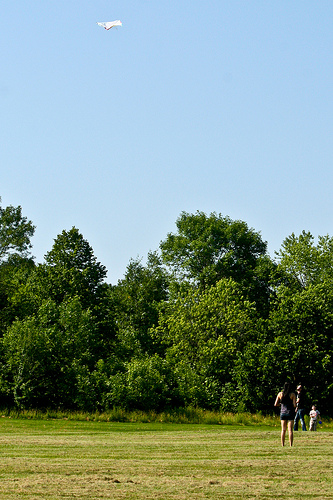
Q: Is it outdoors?
A: Yes, it is outdoors.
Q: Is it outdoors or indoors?
A: It is outdoors.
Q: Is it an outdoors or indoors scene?
A: It is outdoors.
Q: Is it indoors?
A: No, it is outdoors.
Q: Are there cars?
A: No, there are no cars.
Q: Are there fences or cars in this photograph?
A: No, there are no cars or fences.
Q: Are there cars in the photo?
A: No, there are no cars.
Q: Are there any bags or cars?
A: No, there are no cars or bags.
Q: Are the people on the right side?
A: Yes, the people are on the right of the image.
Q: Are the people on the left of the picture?
A: No, the people are on the right of the image.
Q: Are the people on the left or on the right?
A: The people are on the right of the image.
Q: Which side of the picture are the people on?
A: The people are on the right of the image.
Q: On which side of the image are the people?
A: The people are on the right of the image.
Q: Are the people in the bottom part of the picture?
A: Yes, the people are in the bottom of the image.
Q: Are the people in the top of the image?
A: No, the people are in the bottom of the image.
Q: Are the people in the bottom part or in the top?
A: The people are in the bottom of the image.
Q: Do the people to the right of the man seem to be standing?
A: Yes, the people are standing.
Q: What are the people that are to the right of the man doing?
A: The people are standing.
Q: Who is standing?
A: The people are standing.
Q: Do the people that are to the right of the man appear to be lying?
A: No, the people are standing.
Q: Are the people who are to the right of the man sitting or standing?
A: The people are standing.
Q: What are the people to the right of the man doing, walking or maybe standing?
A: The people are standing.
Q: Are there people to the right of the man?
A: Yes, there are people to the right of the man.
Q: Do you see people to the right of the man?
A: Yes, there are people to the right of the man.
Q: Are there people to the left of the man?
A: No, the people are to the right of the man.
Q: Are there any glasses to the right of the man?
A: No, there are people to the right of the man.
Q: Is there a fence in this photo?
A: No, there are no fences.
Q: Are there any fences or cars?
A: No, there are no fences or cars.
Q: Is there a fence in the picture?
A: No, there are no fences.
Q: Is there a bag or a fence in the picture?
A: No, there are no fences or bags.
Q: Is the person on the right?
A: Yes, the person is on the right of the image.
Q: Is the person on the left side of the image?
A: No, the person is on the right of the image.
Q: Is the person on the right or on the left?
A: The person is on the right of the image.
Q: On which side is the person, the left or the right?
A: The person is on the right of the image.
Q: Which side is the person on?
A: The person is on the right of the image.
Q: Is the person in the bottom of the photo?
A: Yes, the person is in the bottom of the image.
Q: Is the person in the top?
A: No, the person is in the bottom of the image.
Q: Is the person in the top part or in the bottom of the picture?
A: The person is in the bottom of the image.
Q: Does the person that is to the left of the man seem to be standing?
A: Yes, the person is standing.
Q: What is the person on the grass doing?
A: The person is standing.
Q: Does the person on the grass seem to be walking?
A: No, the person is standing.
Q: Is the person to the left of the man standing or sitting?
A: The person is standing.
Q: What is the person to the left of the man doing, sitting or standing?
A: The person is standing.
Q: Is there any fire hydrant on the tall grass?
A: No, there is a person on the grass.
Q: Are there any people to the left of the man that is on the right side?
A: Yes, there is a person to the left of the man.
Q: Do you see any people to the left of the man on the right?
A: Yes, there is a person to the left of the man.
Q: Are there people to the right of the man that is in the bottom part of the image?
A: No, the person is to the left of the man.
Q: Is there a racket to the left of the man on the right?
A: No, there is a person to the left of the man.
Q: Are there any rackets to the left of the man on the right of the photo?
A: No, there is a person to the left of the man.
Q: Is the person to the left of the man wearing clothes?
A: Yes, the person is wearing clothes.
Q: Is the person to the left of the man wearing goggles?
A: No, the person is wearing clothes.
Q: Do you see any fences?
A: No, there are no fences.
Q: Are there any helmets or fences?
A: No, there are no fences or helmets.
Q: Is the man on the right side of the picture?
A: Yes, the man is on the right of the image.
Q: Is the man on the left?
A: No, the man is on the right of the image.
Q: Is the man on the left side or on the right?
A: The man is on the right of the image.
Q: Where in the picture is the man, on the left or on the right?
A: The man is on the right of the image.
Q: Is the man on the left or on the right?
A: The man is on the right of the image.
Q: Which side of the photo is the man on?
A: The man is on the right of the image.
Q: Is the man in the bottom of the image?
A: Yes, the man is in the bottom of the image.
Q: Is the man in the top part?
A: No, the man is in the bottom of the image.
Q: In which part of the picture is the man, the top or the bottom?
A: The man is in the bottom of the image.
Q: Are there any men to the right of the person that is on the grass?
A: Yes, there is a man to the right of the person.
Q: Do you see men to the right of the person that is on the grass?
A: Yes, there is a man to the right of the person.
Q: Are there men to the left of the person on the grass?
A: No, the man is to the right of the person.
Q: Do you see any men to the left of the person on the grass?
A: No, the man is to the right of the person.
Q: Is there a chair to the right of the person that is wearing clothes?
A: No, there is a man to the right of the person.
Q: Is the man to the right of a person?
A: Yes, the man is to the right of a person.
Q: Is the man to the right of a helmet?
A: No, the man is to the right of a person.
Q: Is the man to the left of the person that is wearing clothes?
A: No, the man is to the right of the person.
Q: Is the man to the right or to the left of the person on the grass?
A: The man is to the right of the person.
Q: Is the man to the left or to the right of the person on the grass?
A: The man is to the right of the person.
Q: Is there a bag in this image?
A: No, there are no bags.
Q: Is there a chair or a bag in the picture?
A: No, there are no bags or chairs.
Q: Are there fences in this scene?
A: No, there are no fences.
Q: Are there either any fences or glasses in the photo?
A: No, there are no fences or glasses.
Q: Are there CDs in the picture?
A: No, there are no cds.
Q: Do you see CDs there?
A: No, there are no cds.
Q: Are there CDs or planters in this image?
A: No, there are no CDs or planters.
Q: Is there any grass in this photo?
A: Yes, there is grass.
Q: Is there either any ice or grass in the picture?
A: Yes, there is grass.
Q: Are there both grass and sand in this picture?
A: No, there is grass but no sand.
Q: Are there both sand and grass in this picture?
A: No, there is grass but no sand.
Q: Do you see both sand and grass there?
A: No, there is grass but no sand.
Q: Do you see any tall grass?
A: Yes, there is tall grass.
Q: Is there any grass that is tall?
A: Yes, there is grass that is tall.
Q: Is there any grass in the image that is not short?
A: Yes, there is tall grass.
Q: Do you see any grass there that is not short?
A: Yes, there is tall grass.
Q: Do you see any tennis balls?
A: No, there are no tennis balls.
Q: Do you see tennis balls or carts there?
A: No, there are no tennis balls or carts.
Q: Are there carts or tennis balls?
A: No, there are no tennis balls or carts.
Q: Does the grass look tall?
A: Yes, the grass is tall.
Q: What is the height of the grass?
A: The grass is tall.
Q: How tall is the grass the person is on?
A: The grass is tall.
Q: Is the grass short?
A: No, the grass is tall.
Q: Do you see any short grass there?
A: No, there is grass but it is tall.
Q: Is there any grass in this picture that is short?
A: No, there is grass but it is tall.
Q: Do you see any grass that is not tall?
A: No, there is grass but it is tall.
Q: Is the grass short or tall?
A: The grass is tall.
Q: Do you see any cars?
A: No, there are no cars.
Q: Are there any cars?
A: No, there are no cars.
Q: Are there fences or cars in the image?
A: No, there are no cars or fences.